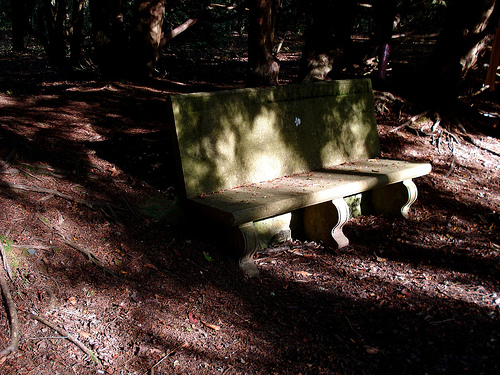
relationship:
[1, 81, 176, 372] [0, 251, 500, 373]
red color in soil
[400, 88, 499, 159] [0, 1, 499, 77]
roots from trees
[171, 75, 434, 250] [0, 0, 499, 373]
shadows on bench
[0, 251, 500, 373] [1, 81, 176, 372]
dry leaves on ground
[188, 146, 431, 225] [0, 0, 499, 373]
dirt on bench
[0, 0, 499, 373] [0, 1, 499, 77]
sunlight streaming through trees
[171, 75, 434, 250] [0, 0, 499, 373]
grey bench in woods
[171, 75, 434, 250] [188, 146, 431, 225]
bench has fallen leaves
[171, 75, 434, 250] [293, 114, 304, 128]
bench has a spot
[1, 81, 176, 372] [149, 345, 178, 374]
ground covered with twigs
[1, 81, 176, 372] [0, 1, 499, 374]
ground with shadows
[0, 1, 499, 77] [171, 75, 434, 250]
branches around bench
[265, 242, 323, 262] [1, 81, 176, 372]
stick on ground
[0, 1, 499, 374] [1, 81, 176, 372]
shadows on ground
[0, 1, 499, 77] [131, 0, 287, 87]
trees with brown trunks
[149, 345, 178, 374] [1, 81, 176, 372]
twig on ground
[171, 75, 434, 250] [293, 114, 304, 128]
bench has a flower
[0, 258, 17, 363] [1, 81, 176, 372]
roots protruding through ground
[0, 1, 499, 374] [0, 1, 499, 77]
shadows in trees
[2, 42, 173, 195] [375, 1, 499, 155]
foliage on forest floor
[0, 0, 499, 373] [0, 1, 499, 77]
sunlight showing through trees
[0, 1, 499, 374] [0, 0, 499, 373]
shadows in forest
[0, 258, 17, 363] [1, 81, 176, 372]
roots on ground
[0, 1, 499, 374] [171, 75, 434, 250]
shadows on bench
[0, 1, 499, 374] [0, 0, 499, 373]
shadows on forest floor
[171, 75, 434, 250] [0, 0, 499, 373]
bench in woods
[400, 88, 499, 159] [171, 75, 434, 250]
roots near bench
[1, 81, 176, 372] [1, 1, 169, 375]
dirt on forest floor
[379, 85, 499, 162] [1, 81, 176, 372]
rocks and dirt on ground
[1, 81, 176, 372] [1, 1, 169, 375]
ground has rotting foliage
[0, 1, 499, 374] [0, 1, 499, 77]
shadows in forest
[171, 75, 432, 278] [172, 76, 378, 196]
bench has moss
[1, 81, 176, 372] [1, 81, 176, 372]
ground covered with leaves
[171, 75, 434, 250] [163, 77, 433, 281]
shadows of trees on bench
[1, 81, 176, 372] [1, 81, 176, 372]
rotting leaves on ground